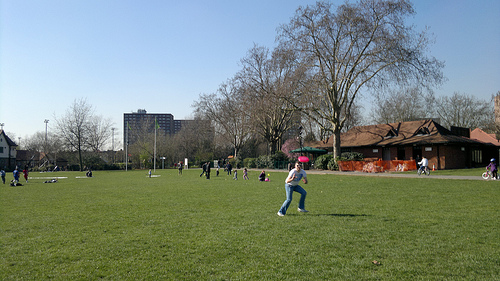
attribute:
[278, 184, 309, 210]
jeans — blue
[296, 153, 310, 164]
frisbee — floating, red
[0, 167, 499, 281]
field — large, open, park area, 'all sports'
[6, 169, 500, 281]
grass — green, short, flat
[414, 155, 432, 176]
person — man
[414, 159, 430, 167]
shirt — white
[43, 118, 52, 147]
light pole — for evening use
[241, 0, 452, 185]
tree — grey, mostly bare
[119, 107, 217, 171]
building — multi-story, office building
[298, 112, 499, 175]
building — single story, park office, under construction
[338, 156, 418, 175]
fence — red, maybe banner, construction netting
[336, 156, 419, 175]
construction netting — orange, tagged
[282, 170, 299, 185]
arm — right arm, bent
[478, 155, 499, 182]
child — little girl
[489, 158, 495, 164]
bicycle helmet — safety helmet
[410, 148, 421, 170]
door — brown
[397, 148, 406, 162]
door — brown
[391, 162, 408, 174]
tag — graffiti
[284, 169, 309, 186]
shirt — t-shirt, white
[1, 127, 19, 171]
building — white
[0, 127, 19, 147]
roof — peaked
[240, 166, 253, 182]
child — young, playing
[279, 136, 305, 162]
tree — flowering tree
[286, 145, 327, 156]
umbrella — open, for shade, green, maybe awning [?]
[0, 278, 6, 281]
sentence — idiotic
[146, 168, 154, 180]
child — standing alone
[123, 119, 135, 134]
flag — flying